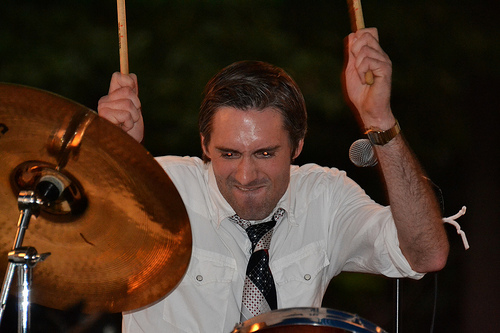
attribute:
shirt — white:
[151, 148, 381, 332]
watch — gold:
[359, 114, 403, 150]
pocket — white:
[269, 241, 338, 332]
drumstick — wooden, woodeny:
[102, 2, 142, 100]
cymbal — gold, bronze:
[4, 87, 163, 328]